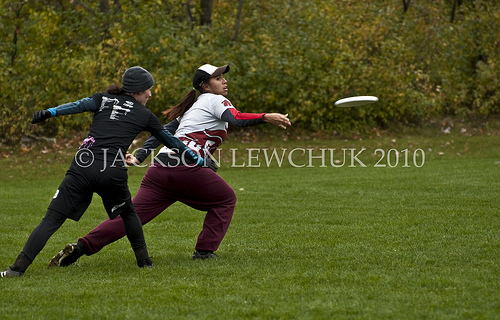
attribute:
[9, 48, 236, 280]
women — playing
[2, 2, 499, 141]
trees — green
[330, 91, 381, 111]
frisbee — high, round, white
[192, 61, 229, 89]
cap — black, white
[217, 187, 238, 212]
knee — bent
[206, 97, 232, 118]
sleeve — red, white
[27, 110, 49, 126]
glove — black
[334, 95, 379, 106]
frisbee — white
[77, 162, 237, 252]
sweatpants — burgundy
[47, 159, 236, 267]
sweatpants — burgundy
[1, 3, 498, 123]
leaves — green, yellow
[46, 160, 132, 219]
shorts — black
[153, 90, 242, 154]
shirt — white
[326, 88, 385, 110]
frisbee — white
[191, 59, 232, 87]
hat — white, brown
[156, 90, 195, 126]
pony tail — brown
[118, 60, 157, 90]
cap — gray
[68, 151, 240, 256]
sweat pants — maroon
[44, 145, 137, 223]
shorts — black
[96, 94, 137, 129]
letters — white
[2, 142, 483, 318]
grass — green, long, fresh, alive, short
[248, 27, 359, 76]
leaves — green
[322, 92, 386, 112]
frisbee — white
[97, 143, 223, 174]
text — white